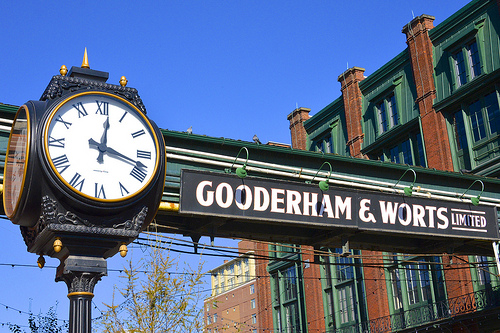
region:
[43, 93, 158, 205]
A big black street clock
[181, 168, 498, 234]
A large company sign board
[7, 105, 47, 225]
A big orange and black signboard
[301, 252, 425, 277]
Long brown electricity cables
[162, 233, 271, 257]
Long brown electricity cables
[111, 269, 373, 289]
Long brown electricity cables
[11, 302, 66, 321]
Long brown electricity cables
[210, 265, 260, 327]
A tall brown and yellow building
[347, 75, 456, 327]
A tall green and brown house wall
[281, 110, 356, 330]
A tall green and brown house wall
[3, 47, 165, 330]
A large street clock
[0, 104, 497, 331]
The company's gate entrance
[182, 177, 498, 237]
The printed company name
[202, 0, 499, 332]
The high storey building block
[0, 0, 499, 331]
The clear blue sky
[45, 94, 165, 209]
The clock reading few minutes after noon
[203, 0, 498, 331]
The brown and green building block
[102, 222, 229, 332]
The yellow growing plant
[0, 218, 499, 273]
The dark cables in the background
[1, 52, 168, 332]
A gray clock post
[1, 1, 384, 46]
the sky is blue and clear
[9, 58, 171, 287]
the clock on the pole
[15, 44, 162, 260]
the clock is art deco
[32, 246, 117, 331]
the pole is corinthian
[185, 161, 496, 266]
the sign is hanging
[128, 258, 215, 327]
the branches are sparse with leaves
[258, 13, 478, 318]
the building is brick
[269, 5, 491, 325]
the building is brown and green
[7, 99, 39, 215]
the clock on the pole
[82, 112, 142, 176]
the hands on the clock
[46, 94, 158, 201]
A white clock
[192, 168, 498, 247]
A white advertisement on a black sign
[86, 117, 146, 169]
Two hands on a clock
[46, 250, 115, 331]
The black post of a clock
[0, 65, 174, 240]
A clock with many faces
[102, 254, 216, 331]
The top of a yellow tree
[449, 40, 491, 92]
A window on a green building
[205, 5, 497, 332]
Buildings by the street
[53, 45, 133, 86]
Golden posts on the top of the clock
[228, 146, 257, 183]
A small bent light over the sign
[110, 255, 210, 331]
a tree with yellow leaves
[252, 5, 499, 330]
The green building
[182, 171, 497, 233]
an advertising sign for Gooderham and Worts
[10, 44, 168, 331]
a clock on a pole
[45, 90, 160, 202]
The front face of the clock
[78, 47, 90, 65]
small gold spear on top of the clock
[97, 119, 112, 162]
hour hand on the clock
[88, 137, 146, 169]
minute hand on the clock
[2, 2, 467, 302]
clear blue sky above with no clouds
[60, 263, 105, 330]
a black pole holding a clock